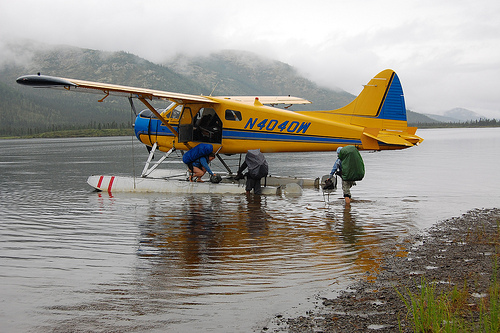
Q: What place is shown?
A: It is a lake.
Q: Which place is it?
A: It is a lake.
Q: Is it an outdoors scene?
A: Yes, it is outdoors.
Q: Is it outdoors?
A: Yes, it is outdoors.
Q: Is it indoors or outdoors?
A: It is outdoors.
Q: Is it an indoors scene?
A: No, it is outdoors.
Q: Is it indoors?
A: No, it is outdoors.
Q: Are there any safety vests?
A: No, there are no safety vests.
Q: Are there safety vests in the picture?
A: No, there are no safety vests.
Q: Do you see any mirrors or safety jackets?
A: No, there are no safety jackets or mirrors.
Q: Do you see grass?
A: Yes, there is grass.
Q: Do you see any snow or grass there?
A: Yes, there is grass.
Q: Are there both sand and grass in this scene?
A: No, there is grass but no sand.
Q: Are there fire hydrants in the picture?
A: No, there are no fire hydrants.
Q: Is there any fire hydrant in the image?
A: No, there are no fire hydrants.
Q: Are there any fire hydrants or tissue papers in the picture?
A: No, there are no fire hydrants or tissue papers.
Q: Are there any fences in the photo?
A: No, there are no fences.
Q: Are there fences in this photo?
A: No, there are no fences.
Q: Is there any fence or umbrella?
A: No, there are no fences or umbrellas.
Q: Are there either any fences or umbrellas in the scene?
A: No, there are no fences or umbrellas.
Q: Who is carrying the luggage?
A: The people are carrying the luggage.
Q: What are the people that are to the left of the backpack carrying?
A: The people are carrying luggage.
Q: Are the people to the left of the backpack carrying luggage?
A: Yes, the people are carrying luggage.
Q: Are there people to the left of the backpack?
A: Yes, there are people to the left of the backpack.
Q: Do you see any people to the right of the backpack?
A: No, the people are to the left of the backpack.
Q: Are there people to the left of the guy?
A: Yes, there are people to the left of the guy.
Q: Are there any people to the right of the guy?
A: No, the people are to the left of the guy.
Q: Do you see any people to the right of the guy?
A: No, the people are to the left of the guy.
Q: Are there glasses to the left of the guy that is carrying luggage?
A: No, there are people to the left of the guy.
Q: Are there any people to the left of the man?
A: Yes, there are people to the left of the man.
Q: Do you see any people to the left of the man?
A: Yes, there are people to the left of the man.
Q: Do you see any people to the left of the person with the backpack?
A: Yes, there are people to the left of the man.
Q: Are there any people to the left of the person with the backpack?
A: Yes, there are people to the left of the man.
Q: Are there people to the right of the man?
A: No, the people are to the left of the man.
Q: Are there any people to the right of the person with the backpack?
A: No, the people are to the left of the man.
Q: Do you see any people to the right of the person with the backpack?
A: No, the people are to the left of the man.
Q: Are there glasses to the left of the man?
A: No, there are people to the left of the man.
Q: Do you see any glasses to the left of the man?
A: No, there are people to the left of the man.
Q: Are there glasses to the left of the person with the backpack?
A: No, there are people to the left of the man.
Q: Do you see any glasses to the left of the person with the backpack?
A: No, there are people to the left of the man.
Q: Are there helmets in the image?
A: No, there are no helmets.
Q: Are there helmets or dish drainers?
A: No, there are no helmets or dish drainers.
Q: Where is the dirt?
A: The dirt is on the lake.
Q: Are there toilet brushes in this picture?
A: No, there are no toilet brushes.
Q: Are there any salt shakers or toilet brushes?
A: No, there are no toilet brushes or salt shakers.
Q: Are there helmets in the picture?
A: No, there are no helmets.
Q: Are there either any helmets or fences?
A: No, there are no helmets or fences.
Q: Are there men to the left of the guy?
A: Yes, there is a man to the left of the guy.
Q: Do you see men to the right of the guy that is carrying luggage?
A: No, the man is to the left of the guy.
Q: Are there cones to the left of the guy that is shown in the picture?
A: No, there is a man to the left of the guy.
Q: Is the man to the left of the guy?
A: Yes, the man is to the left of the guy.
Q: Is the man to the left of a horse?
A: No, the man is to the left of the guy.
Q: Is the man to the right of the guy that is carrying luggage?
A: No, the man is to the left of the guy.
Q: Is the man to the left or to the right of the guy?
A: The man is to the left of the guy.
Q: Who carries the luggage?
A: The man carries the luggage.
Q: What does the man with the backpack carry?
A: The man carries luggage.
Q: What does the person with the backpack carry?
A: The man carries luggage.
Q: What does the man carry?
A: The man carries luggage.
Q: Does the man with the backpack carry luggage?
A: Yes, the man carries luggage.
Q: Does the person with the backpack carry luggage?
A: Yes, the man carries luggage.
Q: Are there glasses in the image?
A: No, there are no glasses.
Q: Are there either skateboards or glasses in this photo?
A: No, there are no glasses or skateboards.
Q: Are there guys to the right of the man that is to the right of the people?
A: Yes, there is a guy to the right of the man.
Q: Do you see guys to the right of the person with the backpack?
A: Yes, there is a guy to the right of the man.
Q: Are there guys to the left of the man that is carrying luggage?
A: No, the guy is to the right of the man.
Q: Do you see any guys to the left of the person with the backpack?
A: No, the guy is to the right of the man.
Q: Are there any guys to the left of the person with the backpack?
A: No, the guy is to the right of the man.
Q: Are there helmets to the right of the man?
A: No, there is a guy to the right of the man.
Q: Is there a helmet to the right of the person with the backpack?
A: No, there is a guy to the right of the man.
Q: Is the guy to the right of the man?
A: Yes, the guy is to the right of the man.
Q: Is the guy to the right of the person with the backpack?
A: Yes, the guy is to the right of the man.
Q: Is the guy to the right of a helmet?
A: No, the guy is to the right of the man.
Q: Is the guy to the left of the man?
A: No, the guy is to the right of the man.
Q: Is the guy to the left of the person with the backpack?
A: No, the guy is to the right of the man.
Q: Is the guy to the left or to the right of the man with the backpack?
A: The guy is to the right of the man.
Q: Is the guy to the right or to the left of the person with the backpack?
A: The guy is to the right of the man.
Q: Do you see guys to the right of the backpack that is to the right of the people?
A: Yes, there is a guy to the right of the backpack.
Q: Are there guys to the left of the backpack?
A: No, the guy is to the right of the backpack.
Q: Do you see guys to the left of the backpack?
A: No, the guy is to the right of the backpack.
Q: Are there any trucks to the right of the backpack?
A: No, there is a guy to the right of the backpack.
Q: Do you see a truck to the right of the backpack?
A: No, there is a guy to the right of the backpack.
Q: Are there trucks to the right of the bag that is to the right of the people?
A: No, there is a guy to the right of the backpack.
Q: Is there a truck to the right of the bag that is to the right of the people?
A: No, there is a guy to the right of the backpack.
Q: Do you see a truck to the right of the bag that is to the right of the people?
A: No, there is a guy to the right of the backpack.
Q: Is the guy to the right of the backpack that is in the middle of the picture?
A: Yes, the guy is to the right of the backpack.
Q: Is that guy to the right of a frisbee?
A: No, the guy is to the right of the backpack.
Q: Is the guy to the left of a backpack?
A: No, the guy is to the right of a backpack.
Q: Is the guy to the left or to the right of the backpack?
A: The guy is to the right of the backpack.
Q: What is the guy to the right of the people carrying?
A: The guy is carrying luggage.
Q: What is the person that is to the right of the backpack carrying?
A: The guy is carrying luggage.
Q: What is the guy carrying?
A: The guy is carrying luggage.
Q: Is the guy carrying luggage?
A: Yes, the guy is carrying luggage.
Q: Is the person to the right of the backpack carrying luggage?
A: Yes, the guy is carrying luggage.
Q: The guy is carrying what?
A: The guy is carrying luggage.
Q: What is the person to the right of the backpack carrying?
A: The guy is carrying luggage.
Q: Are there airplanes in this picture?
A: Yes, there is an airplane.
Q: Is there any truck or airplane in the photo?
A: Yes, there is an airplane.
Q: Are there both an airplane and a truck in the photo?
A: No, there is an airplane but no trucks.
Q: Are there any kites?
A: No, there are no kites.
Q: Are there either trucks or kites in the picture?
A: No, there are no kites or trucks.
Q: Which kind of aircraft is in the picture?
A: The aircraft is an airplane.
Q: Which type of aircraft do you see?
A: The aircraft is an airplane.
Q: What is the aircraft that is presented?
A: The aircraft is an airplane.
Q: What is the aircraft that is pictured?
A: The aircraft is an airplane.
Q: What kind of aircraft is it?
A: The aircraft is an airplane.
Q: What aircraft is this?
A: This is an airplane.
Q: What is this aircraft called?
A: This is an airplane.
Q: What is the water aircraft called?
A: The aircraft is an airplane.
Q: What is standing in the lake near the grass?
A: The airplane is standing in the lake.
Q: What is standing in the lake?
A: The airplane is standing in the lake.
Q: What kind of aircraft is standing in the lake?
A: The aircraft is an airplane.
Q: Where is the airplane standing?
A: The airplane is standing in the lake.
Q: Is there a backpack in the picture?
A: Yes, there is a backpack.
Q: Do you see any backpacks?
A: Yes, there is a backpack.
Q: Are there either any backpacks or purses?
A: Yes, there is a backpack.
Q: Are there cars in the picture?
A: No, there are no cars.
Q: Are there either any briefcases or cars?
A: No, there are no cars or briefcases.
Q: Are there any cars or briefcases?
A: No, there are no cars or briefcases.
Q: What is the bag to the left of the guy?
A: The bag is a backpack.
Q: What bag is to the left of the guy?
A: The bag is a backpack.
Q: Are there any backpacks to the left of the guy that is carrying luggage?
A: Yes, there is a backpack to the left of the guy.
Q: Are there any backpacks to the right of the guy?
A: No, the backpack is to the left of the guy.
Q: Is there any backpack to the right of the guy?
A: No, the backpack is to the left of the guy.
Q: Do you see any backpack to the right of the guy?
A: No, the backpack is to the left of the guy.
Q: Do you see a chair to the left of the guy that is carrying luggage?
A: No, there is a backpack to the left of the guy.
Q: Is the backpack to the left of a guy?
A: Yes, the backpack is to the left of a guy.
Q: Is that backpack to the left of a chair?
A: No, the backpack is to the left of a guy.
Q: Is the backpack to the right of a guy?
A: No, the backpack is to the left of a guy.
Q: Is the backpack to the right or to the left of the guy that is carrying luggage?
A: The backpack is to the left of the guy.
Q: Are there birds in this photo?
A: No, there are no birds.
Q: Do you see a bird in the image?
A: No, there are no birds.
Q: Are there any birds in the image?
A: No, there are no birds.